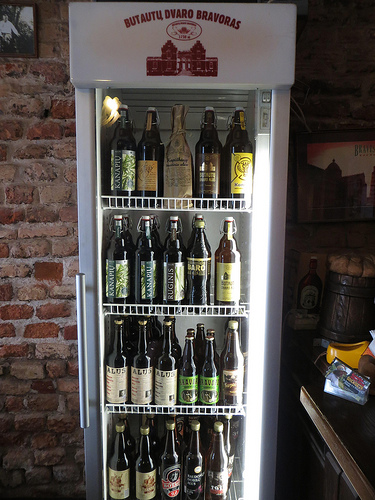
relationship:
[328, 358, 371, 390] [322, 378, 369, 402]
cards sitting container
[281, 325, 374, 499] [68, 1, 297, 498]
counter near cooler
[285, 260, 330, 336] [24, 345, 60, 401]
box near wall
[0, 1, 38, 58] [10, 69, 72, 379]
photo on wall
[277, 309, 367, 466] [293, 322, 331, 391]
wooden case of liqour